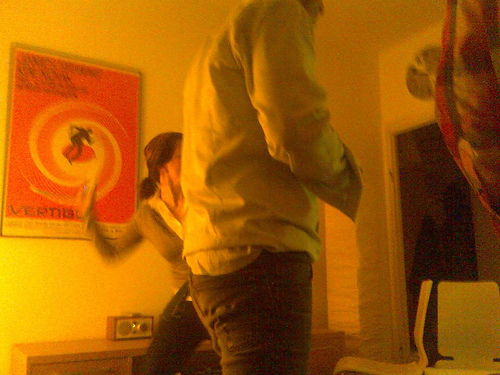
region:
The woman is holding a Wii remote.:
[67, 170, 104, 218]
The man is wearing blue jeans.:
[181, 252, 331, 367]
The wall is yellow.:
[9, 265, 89, 317]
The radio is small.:
[100, 307, 156, 337]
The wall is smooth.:
[10, 252, 84, 316]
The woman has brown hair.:
[134, 130, 181, 198]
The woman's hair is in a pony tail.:
[129, 130, 184, 199]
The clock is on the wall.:
[402, 41, 451, 105]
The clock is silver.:
[404, 40, 441, 103]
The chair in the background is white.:
[427, 282, 499, 374]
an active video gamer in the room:
[80, 130, 210, 374]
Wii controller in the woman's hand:
[78, 158, 105, 218]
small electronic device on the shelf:
[104, 311, 154, 341]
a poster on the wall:
[0, 43, 142, 240]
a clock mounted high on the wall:
[405, 44, 448, 102]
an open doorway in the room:
[390, 123, 499, 361]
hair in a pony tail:
[135, 166, 162, 201]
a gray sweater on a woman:
[86, 192, 189, 289]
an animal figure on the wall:
[62, 123, 99, 168]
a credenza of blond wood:
[10, 327, 346, 372]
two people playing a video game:
[65, 6, 379, 373]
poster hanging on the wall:
[6, 44, 144, 251]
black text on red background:
[14, 50, 111, 224]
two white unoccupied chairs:
[342, 272, 499, 373]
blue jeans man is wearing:
[182, 253, 303, 373]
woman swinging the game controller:
[53, 132, 235, 373]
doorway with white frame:
[391, 124, 491, 372]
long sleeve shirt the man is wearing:
[185, 12, 352, 248]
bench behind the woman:
[18, 322, 353, 374]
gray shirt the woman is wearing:
[95, 199, 190, 289]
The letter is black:
[6, 197, 23, 223]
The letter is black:
[21, 200, 36, 220]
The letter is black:
[34, 198, 48, 223]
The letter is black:
[47, 198, 57, 223]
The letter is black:
[51, 202, 62, 223]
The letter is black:
[61, 199, 73, 225]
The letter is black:
[71, 205, 81, 220]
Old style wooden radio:
[93, 300, 160, 348]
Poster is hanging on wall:
[3, 37, 150, 257]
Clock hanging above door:
[371, 40, 481, 157]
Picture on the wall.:
[2, 37, 147, 252]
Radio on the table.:
[100, 304, 160, 344]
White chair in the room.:
[430, 273, 498, 373]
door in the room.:
[389, 119, 479, 360]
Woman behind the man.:
[82, 118, 208, 374]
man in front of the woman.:
[172, 0, 363, 373]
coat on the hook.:
[406, 205, 446, 298]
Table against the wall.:
[12, 319, 347, 374]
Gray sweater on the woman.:
[71, 114, 206, 301]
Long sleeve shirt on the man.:
[160, 2, 372, 262]